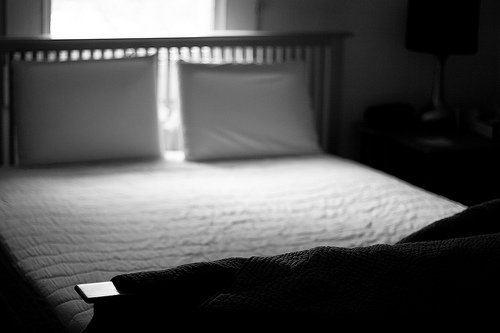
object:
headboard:
[0, 28, 352, 165]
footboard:
[78, 279, 124, 301]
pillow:
[175, 59, 321, 162]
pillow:
[10, 55, 161, 167]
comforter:
[2, 156, 474, 330]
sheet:
[3, 156, 468, 323]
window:
[41, 0, 222, 153]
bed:
[2, 27, 499, 332]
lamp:
[400, 0, 498, 127]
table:
[349, 114, 499, 193]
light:
[46, 0, 216, 37]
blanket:
[76, 196, 498, 331]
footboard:
[75, 230, 497, 317]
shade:
[400, 1, 482, 57]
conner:
[68, 280, 108, 328]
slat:
[0, 31, 347, 49]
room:
[2, 1, 499, 331]